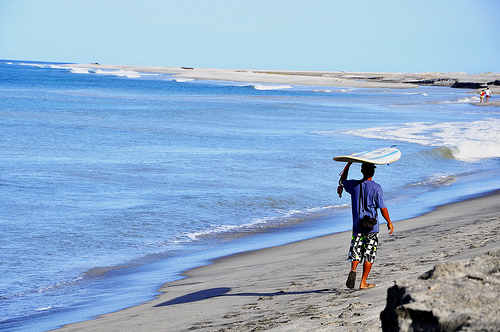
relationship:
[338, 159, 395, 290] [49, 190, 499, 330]
he walking on beach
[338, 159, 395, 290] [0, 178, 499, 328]
he walks on shore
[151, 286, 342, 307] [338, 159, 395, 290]
shadow of he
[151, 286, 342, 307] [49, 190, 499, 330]
shadow on beach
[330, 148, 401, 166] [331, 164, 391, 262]
surfboard on man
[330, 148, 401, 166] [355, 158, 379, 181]
surfboard on head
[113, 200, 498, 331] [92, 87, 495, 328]
sand covering beach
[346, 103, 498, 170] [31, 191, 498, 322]
wave crashing on shore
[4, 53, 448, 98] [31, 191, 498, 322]
wave crashing on shore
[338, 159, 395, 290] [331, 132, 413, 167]
he carrying board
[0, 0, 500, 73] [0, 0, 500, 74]
clouds in sky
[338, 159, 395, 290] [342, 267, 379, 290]
he wearing flip flops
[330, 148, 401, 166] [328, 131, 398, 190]
surfboard has stripes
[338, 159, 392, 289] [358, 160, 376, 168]
he wearing a baseball cap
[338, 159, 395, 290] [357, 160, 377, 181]
he walking with surfboard on h head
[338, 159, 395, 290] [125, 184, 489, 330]
he walking across beach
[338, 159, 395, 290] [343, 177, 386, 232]
he wearing shirt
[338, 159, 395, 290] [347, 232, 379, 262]
he wearing shorts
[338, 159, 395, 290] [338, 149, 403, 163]
he carrying surfboard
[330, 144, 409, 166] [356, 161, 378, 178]
surfboard on head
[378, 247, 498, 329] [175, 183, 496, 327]
rock on beach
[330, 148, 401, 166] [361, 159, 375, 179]
surfboard of head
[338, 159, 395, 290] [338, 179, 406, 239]
he wearing shirt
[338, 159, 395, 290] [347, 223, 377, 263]
he wearing shorts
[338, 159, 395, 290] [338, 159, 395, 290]
he a he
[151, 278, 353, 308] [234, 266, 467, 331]
shadow on ground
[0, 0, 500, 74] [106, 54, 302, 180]
sky completely free of clouds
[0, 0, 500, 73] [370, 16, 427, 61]
clouds in sky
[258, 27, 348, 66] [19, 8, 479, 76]
clouds in sky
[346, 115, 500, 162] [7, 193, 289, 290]
wave coming to shore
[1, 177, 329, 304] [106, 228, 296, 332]
tide going in and out